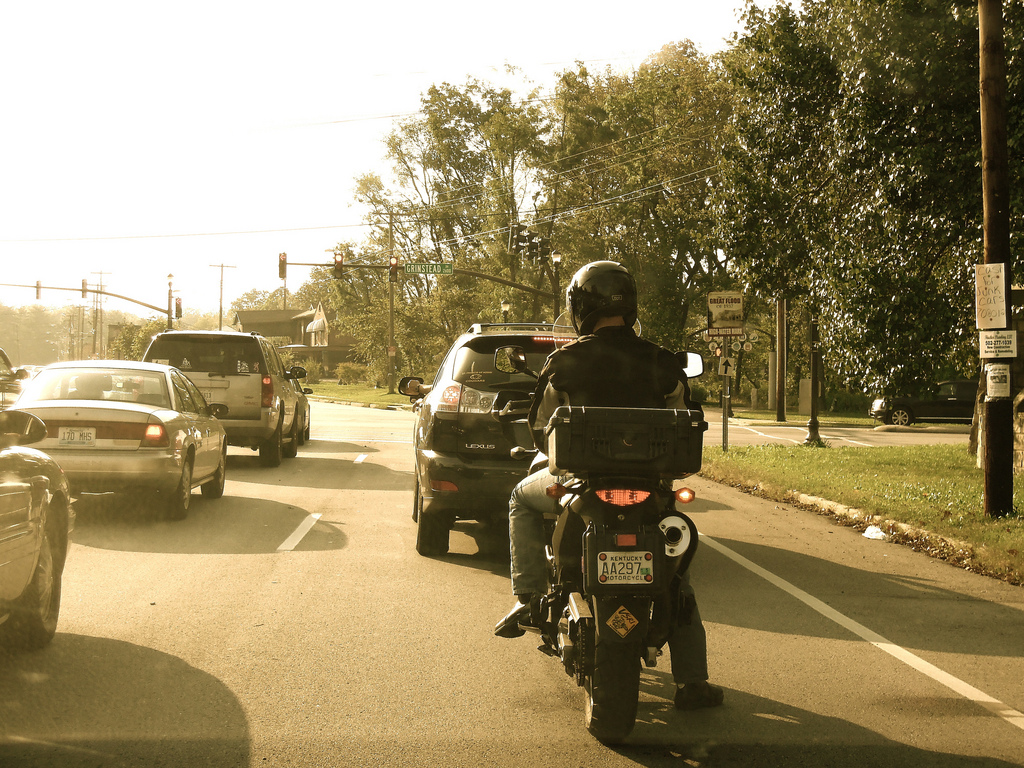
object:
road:
[0, 398, 1024, 768]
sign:
[723, 377, 730, 453]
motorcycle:
[488, 345, 708, 743]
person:
[491, 260, 725, 710]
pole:
[278, 252, 555, 302]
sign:
[975, 262, 1007, 329]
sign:
[979, 331, 1017, 359]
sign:
[987, 364, 1010, 397]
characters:
[602, 556, 647, 581]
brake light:
[41, 421, 170, 448]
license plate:
[58, 427, 97, 446]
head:
[566, 260, 638, 337]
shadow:
[72, 493, 347, 554]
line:
[694, 532, 1024, 738]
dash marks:
[277, 512, 323, 550]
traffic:
[0, 250, 1024, 768]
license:
[597, 551, 654, 584]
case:
[544, 406, 709, 480]